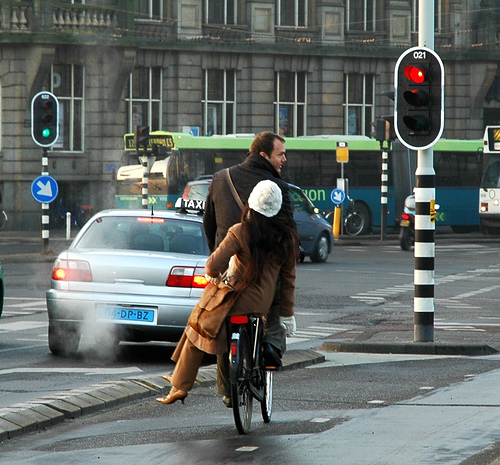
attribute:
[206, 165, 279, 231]
jacket — black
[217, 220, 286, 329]
coat — brown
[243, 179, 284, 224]
hat — white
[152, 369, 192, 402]
shoes — brown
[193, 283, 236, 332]
bag — brown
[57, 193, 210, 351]
car — silver